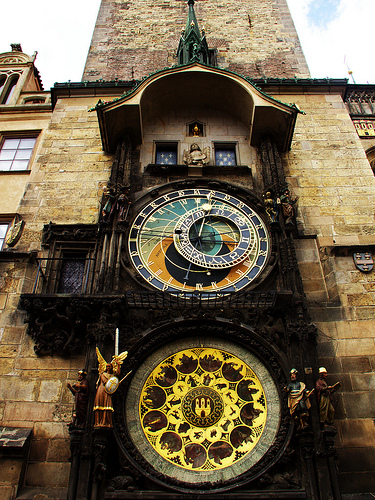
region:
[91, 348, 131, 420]
a gold angel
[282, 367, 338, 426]
two statues on the wall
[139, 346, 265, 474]
a round decorative gold piece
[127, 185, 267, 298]
a large clock on the building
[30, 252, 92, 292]
a metal balcony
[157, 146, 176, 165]
the window is blue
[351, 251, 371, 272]
a shield on the wall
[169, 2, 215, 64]
a green tower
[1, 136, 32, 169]
the window is closed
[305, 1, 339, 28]
a blue patch of sky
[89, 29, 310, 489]
A clock tower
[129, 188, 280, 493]
There are two clock faces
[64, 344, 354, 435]
Miniature people on the clock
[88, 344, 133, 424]
This person has wings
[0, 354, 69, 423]
The tower is made of brick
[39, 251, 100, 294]
A small fence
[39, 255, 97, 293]
The fence is made of metal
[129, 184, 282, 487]
The clock faces are circular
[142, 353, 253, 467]
This clock is made partially of gold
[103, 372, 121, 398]
This person is holding a shield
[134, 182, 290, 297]
a clock on a castle's wall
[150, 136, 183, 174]
the window of a castle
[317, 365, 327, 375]
the head of a person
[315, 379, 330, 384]
a hand of a person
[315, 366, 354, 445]
a person standing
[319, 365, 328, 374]
a hat worn by a person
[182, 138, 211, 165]
a sketch of a man on the wall of a castle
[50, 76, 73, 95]
the edge of the castle's roof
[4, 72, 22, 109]
a side door of a castle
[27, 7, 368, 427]
a huge castle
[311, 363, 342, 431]
first statue on right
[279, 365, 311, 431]
second statue on right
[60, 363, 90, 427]
first statue on left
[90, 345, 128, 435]
second statue on left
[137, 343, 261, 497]
gold and purple clock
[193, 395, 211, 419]
symbol in middle of clock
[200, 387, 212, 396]
outlining circle around symbol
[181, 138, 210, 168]
statue overtop of clocks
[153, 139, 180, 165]
window on left side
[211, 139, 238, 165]
window on right side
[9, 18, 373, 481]
side of a building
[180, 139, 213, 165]
figure on top of clock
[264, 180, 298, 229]
figures next to clock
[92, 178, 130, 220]
figures next to clock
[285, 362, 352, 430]
figures next to circular piece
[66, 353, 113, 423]
figures next to circular piece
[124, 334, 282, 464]
circular piece under clock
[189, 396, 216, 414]
image of building on circular piece